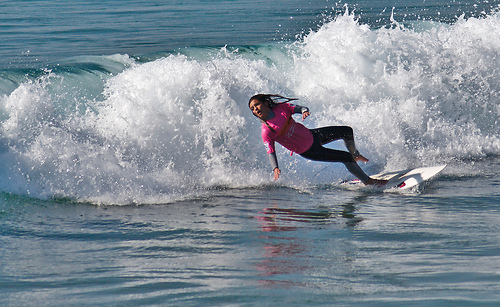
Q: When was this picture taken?
A: Daytime.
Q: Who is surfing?
A: A woman.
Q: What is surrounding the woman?
A: Water.